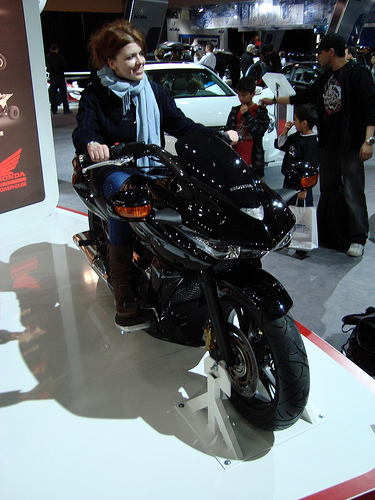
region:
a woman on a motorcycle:
[73, 24, 323, 426]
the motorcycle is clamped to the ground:
[76, 251, 331, 471]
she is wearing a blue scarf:
[92, 65, 164, 151]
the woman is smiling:
[102, 26, 153, 80]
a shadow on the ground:
[0, 237, 285, 468]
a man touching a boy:
[224, 31, 374, 260]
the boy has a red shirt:
[220, 102, 256, 165]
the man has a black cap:
[303, 29, 349, 53]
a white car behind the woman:
[141, 50, 244, 137]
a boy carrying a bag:
[267, 99, 322, 255]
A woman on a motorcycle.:
[76, 17, 175, 330]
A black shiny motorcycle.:
[62, 146, 327, 404]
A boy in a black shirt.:
[276, 104, 323, 257]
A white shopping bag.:
[283, 196, 321, 258]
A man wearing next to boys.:
[306, 37, 367, 250]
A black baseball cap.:
[303, 32, 349, 52]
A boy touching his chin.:
[226, 75, 266, 137]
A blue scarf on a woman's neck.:
[94, 67, 165, 170]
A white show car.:
[141, 63, 267, 158]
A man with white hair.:
[241, 40, 255, 59]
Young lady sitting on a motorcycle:
[71, 24, 239, 161]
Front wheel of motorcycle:
[210, 307, 309, 428]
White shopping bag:
[285, 204, 319, 250]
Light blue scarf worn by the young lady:
[95, 68, 156, 167]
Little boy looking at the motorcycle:
[225, 75, 270, 172]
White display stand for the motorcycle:
[171, 370, 242, 455]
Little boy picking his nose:
[271, 99, 317, 204]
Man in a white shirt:
[195, 41, 212, 65]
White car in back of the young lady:
[143, 67, 233, 97]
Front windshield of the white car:
[142, 67, 237, 98]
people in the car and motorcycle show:
[38, 15, 373, 498]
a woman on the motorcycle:
[67, 19, 321, 432]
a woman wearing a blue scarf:
[69, 15, 177, 139]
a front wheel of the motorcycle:
[203, 290, 312, 435]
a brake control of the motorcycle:
[81, 159, 127, 174]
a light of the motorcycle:
[106, 188, 153, 221]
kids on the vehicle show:
[222, 76, 317, 257]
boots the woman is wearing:
[105, 243, 141, 317]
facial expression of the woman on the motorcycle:
[111, 39, 147, 81]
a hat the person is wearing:
[312, 33, 346, 52]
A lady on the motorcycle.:
[81, 26, 173, 216]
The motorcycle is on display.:
[73, 188, 348, 430]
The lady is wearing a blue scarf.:
[108, 76, 161, 121]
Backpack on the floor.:
[347, 299, 372, 356]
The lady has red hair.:
[93, 28, 120, 55]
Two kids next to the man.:
[231, 67, 330, 208]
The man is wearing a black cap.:
[316, 26, 343, 52]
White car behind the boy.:
[157, 66, 240, 133]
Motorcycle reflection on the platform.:
[23, 231, 140, 436]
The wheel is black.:
[204, 298, 324, 428]